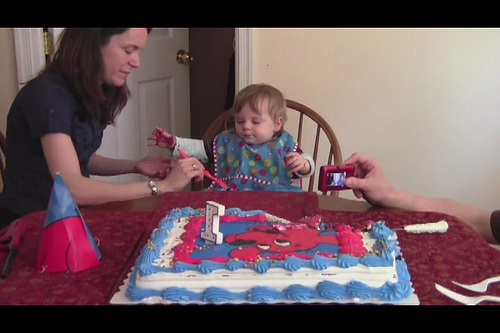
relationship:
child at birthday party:
[211, 83, 302, 190] [26, 169, 486, 308]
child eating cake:
[211, 83, 302, 190] [174, 192, 393, 295]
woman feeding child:
[32, 25, 177, 191] [211, 83, 302, 190]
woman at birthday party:
[32, 25, 177, 191] [26, 169, 486, 308]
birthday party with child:
[26, 169, 486, 308] [211, 83, 302, 190]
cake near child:
[174, 192, 393, 295] [211, 83, 302, 190]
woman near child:
[32, 25, 177, 191] [211, 83, 302, 190]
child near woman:
[211, 83, 302, 190] [32, 25, 177, 191]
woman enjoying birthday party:
[32, 25, 177, 191] [26, 169, 486, 308]